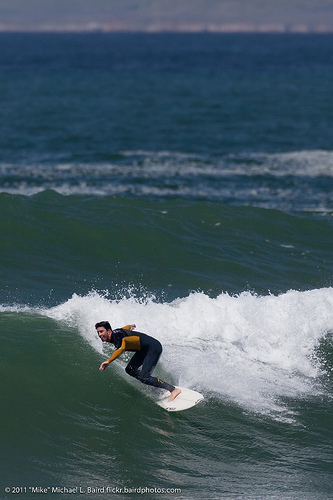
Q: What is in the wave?
A: Someone surfing.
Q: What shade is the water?
A: Blue.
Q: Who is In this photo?
A: A surfer.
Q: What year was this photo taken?
A: 2011.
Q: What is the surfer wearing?
A: A wetsuit.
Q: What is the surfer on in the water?
A: A surfboard.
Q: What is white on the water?
A: Ocean foam.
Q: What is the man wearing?
A: Wetsuit.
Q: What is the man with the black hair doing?
A: Surfing.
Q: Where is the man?
A: Inside a wave.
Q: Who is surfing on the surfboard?
A: A man.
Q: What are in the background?
A: Waves.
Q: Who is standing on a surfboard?
A: Surfer.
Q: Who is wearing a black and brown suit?
A: Surfer.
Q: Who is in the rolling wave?
A: Surfer.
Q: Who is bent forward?
A: Surfer.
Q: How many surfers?
A: One.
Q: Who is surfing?
A: A man.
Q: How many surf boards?
A: One.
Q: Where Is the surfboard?
A: Under man's feet.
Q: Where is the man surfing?
A: Ocean.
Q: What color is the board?
A: White.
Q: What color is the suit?
A: Black.